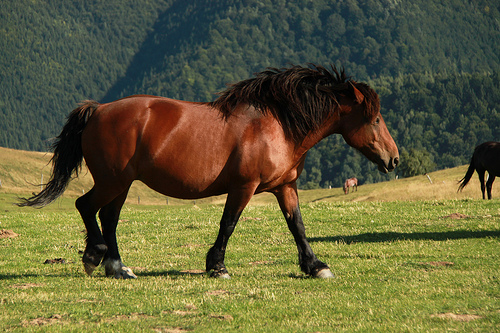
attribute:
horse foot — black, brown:
[292, 247, 334, 284]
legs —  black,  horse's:
[205, 207, 245, 279]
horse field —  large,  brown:
[15, 58, 406, 284]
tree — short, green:
[368, 36, 478, 107]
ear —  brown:
[348, 77, 365, 103]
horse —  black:
[21, 52, 380, 302]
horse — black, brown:
[458, 141, 498, 205]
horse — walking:
[57, 35, 478, 330]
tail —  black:
[7, 97, 97, 199]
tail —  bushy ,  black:
[4, 95, 100, 205]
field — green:
[2, 154, 497, 326]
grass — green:
[234, 228, 291, 300]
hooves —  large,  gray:
[307, 260, 335, 280]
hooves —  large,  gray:
[203, 262, 231, 282]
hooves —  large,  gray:
[108, 266, 135, 280]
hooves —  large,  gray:
[84, 240, 107, 262]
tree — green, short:
[344, 54, 498, 195]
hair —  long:
[15, 100, 95, 210]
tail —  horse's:
[14, 100, 95, 214]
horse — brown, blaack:
[22, 56, 423, 303]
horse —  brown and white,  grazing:
[342, 175, 362, 195]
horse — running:
[65, 21, 431, 241]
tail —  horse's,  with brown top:
[59, 97, 98, 202]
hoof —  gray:
[313, 265, 333, 280]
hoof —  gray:
[205, 263, 232, 281]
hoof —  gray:
[103, 267, 138, 279]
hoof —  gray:
[81, 251, 105, 277]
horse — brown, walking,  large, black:
[12, 62, 401, 287]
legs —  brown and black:
[77, 209, 336, 284]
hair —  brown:
[212, 62, 346, 143]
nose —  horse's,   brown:
[388, 154, 404, 165]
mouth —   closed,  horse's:
[380, 162, 398, 175]